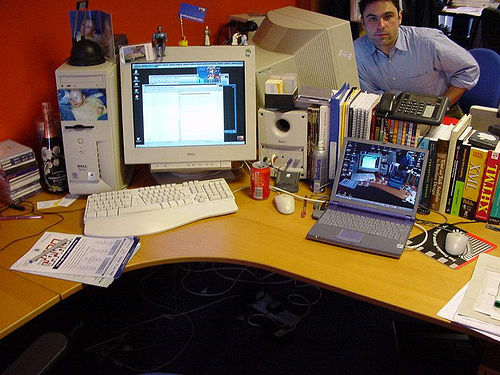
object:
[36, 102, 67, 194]
bottle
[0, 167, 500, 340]
desk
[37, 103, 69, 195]
wine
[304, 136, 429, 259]
laptop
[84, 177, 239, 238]
keyboard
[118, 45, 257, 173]
monitor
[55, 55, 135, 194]
tower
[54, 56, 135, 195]
cpu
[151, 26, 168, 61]
toy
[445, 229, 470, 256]
mouse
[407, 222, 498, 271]
mousepad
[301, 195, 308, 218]
pen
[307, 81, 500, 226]
books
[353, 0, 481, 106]
man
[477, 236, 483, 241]
red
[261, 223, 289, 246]
brown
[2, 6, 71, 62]
wall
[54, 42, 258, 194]
computer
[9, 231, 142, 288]
papers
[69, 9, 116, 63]
picture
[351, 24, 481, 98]
shirt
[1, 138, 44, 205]
stack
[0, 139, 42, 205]
cds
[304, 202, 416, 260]
small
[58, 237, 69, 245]
grey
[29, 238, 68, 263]
pen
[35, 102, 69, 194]
champagne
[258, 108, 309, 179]
sub-woofer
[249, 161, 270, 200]
can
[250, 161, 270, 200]
cola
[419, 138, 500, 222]
row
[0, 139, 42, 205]
discs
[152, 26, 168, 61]
figurine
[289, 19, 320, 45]
white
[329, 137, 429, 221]
screen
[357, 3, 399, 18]
hair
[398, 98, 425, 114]
black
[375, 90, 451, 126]
phone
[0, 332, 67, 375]
armrest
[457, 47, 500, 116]
chair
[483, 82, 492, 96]
blue